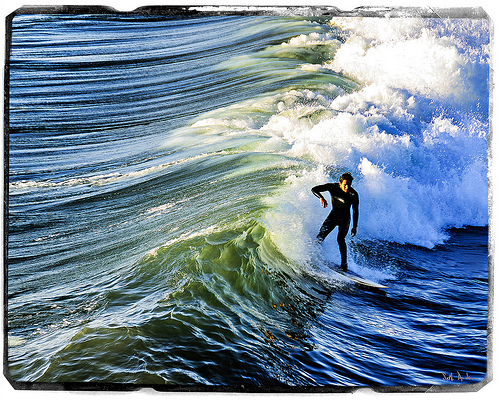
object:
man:
[311, 172, 359, 272]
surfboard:
[321, 261, 390, 290]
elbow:
[311, 186, 319, 193]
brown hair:
[340, 172, 353, 184]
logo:
[337, 196, 345, 203]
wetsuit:
[311, 183, 359, 268]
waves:
[6, 7, 490, 390]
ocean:
[5, 7, 487, 386]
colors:
[229, 246, 246, 262]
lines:
[5, 25, 321, 73]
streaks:
[312, 348, 401, 388]